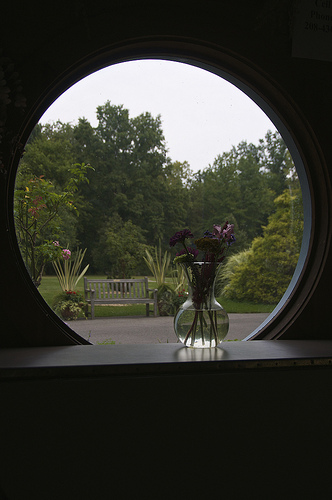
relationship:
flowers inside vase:
[169, 218, 236, 348] [174, 262, 230, 349]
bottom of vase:
[174, 299, 230, 350] [174, 262, 230, 349]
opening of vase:
[182, 259, 220, 269] [174, 262, 230, 349]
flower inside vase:
[207, 220, 234, 245] [174, 262, 230, 349]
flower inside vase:
[169, 229, 193, 252] [174, 262, 230, 349]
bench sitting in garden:
[80, 278, 159, 319] [13, 177, 308, 319]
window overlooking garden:
[15, 57, 312, 340] [13, 177, 308, 319]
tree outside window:
[12, 120, 92, 286] [15, 57, 312, 340]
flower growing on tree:
[60, 249, 70, 259] [12, 120, 92, 286]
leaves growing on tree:
[27, 195, 46, 216] [12, 120, 92, 286]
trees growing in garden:
[16, 101, 297, 277] [13, 177, 308, 319]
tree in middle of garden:
[90, 210, 165, 290] [13, 177, 308, 319]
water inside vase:
[174, 306, 229, 348] [174, 262, 230, 349]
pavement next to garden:
[62, 311, 270, 345] [13, 177, 308, 319]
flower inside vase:
[177, 247, 200, 257] [174, 262, 230, 349]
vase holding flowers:
[174, 262, 230, 349] [169, 218, 236, 348]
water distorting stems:
[174, 306, 229, 348] [185, 309, 220, 347]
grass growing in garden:
[41, 274, 278, 317] [13, 177, 308, 319]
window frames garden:
[15, 57, 312, 340] [13, 177, 308, 319]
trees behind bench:
[16, 101, 297, 277] [80, 278, 159, 319]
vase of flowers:
[174, 262, 230, 349] [169, 218, 236, 348]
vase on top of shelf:
[174, 262, 230, 349] [0, 340, 331, 380]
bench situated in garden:
[80, 278, 159, 319] [13, 177, 308, 319]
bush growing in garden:
[221, 186, 302, 300] [13, 177, 308, 319]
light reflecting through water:
[181, 337, 220, 348] [174, 306, 229, 348]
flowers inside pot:
[65, 290, 76, 296] [57, 290, 81, 304]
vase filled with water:
[174, 262, 230, 349] [174, 306, 229, 348]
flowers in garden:
[65, 290, 76, 296] [13, 177, 308, 319]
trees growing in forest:
[16, 101, 297, 277] [23, 103, 299, 274]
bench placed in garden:
[80, 278, 159, 319] [13, 177, 308, 319]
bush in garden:
[221, 186, 302, 300] [13, 177, 308, 319]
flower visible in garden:
[60, 249, 70, 259] [13, 177, 308, 319]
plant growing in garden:
[48, 247, 90, 320] [13, 177, 308, 319]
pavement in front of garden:
[62, 311, 270, 345] [13, 177, 308, 319]